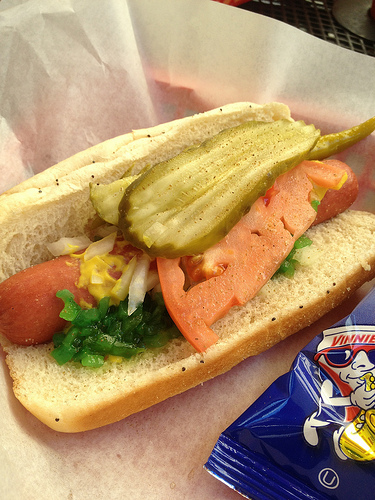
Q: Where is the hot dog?
A: On the white paper.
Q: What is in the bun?
A: A hot dog.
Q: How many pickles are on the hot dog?
A: Two.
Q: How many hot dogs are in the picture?
A: One.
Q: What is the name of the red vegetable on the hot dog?
A: Tomato.